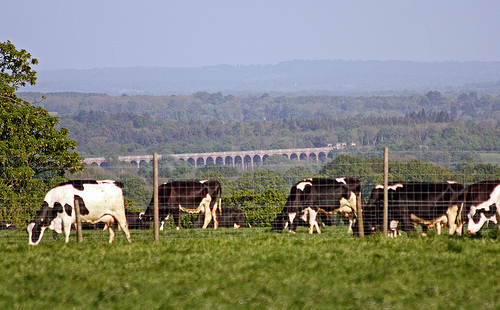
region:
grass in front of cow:
[111, 251, 212, 306]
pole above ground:
[366, 138, 408, 219]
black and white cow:
[253, 170, 363, 251]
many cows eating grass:
[26, 111, 484, 276]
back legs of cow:
[83, 212, 151, 260]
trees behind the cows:
[158, 85, 280, 147]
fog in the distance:
[256, 44, 329, 88]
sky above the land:
[158, 6, 250, 64]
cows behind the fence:
[41, 134, 401, 280]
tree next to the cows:
[0, 92, 80, 149]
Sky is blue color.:
[58, 18, 343, 51]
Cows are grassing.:
[5, 148, 498, 266]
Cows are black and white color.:
[32, 170, 472, 255]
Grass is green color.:
[80, 240, 426, 295]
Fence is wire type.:
[20, 165, 450, 230]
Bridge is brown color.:
[55, 135, 380, 180]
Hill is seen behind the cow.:
[25, 55, 480, 101]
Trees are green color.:
[5, 86, 50, 196]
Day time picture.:
[11, 27, 468, 288]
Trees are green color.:
[11, 102, 486, 235]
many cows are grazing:
[22, 162, 479, 254]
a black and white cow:
[5, 169, 135, 251]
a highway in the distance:
[116, 137, 360, 177]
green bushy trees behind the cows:
[92, 97, 396, 156]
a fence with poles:
[131, 152, 468, 242]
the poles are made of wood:
[133, 140, 171, 253]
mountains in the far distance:
[35, 34, 470, 104]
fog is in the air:
[53, 16, 456, 83]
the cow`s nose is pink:
[461, 225, 475, 239]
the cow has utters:
[311, 202, 361, 224]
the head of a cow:
[17, 210, 54, 251]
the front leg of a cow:
[55, 215, 81, 250]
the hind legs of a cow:
[103, 212, 139, 244]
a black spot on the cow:
[71, 192, 93, 215]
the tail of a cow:
[213, 181, 227, 216]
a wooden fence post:
[143, 145, 169, 245]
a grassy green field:
[2, 226, 499, 308]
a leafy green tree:
[0, 38, 92, 230]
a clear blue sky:
[0, 0, 499, 67]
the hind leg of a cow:
[111, 210, 138, 248]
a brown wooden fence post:
[147, 147, 172, 248]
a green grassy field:
[1, 226, 498, 307]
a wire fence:
[0, 145, 499, 246]